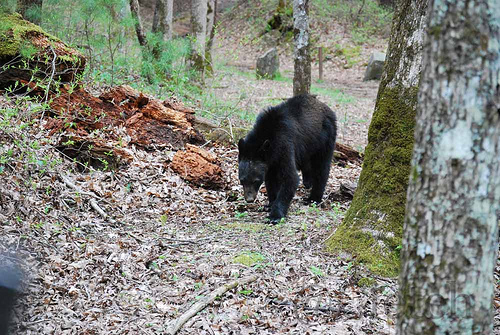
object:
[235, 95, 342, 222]
bear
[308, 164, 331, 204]
leg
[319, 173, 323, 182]
black fur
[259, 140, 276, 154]
ear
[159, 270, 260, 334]
stick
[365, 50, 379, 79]
rock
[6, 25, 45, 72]
woods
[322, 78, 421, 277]
moss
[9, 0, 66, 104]
tree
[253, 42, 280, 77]
stump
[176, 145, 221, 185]
wood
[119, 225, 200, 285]
ground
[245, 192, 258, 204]
nose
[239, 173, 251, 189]
eyes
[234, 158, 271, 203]
head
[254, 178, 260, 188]
eye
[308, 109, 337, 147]
rear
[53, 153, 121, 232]
sticks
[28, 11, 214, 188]
forest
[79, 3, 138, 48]
vines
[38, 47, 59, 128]
branch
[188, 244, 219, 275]
leaves